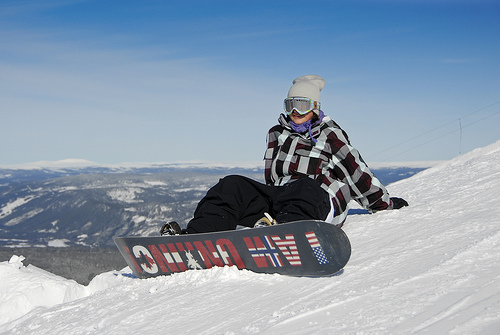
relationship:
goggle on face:
[275, 92, 317, 120] [273, 89, 323, 134]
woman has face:
[159, 73, 410, 240] [273, 89, 323, 134]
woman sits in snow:
[159, 73, 410, 240] [0, 139, 498, 334]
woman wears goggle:
[159, 73, 410, 240] [283, 96, 321, 115]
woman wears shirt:
[159, 73, 410, 240] [264, 114, 392, 226]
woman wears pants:
[159, 73, 410, 240] [184, 177, 329, 233]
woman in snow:
[159, 73, 410, 240] [0, 139, 498, 334]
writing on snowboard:
[121, 230, 329, 274] [108, 216, 354, 281]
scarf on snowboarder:
[274, 113, 335, 140] [174, 79, 427, 259]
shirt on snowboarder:
[242, 111, 413, 225] [161, 74, 409, 242]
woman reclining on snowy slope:
[159, 73, 410, 240] [28, 137, 496, 330]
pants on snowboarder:
[168, 167, 333, 245] [161, 74, 409, 242]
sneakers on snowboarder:
[154, 210, 281, 237] [161, 74, 409, 242]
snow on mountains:
[1, 156, 439, 245] [0, 155, 269, 252]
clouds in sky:
[75, 91, 189, 133] [70, 31, 182, 75]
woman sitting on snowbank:
[159, 73, 410, 240] [407, 158, 494, 335]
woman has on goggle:
[159, 73, 410, 240] [283, 96, 321, 115]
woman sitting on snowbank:
[159, 73, 410, 240] [53, 196, 470, 318]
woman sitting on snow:
[159, 73, 410, 240] [439, 136, 497, 228]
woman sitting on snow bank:
[159, 73, 410, 240] [1, 129, 496, 328]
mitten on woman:
[389, 196, 408, 209] [159, 73, 410, 240]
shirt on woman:
[242, 111, 413, 225] [159, 73, 410, 240]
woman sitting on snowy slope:
[159, 73, 410, 240] [0, 138, 500, 335]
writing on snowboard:
[121, 230, 329, 274] [112, 219, 352, 279]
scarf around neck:
[286, 109, 326, 143] [283, 117, 322, 131]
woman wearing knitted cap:
[159, 73, 410, 240] [279, 72, 326, 116]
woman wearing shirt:
[159, 73, 411, 240] [242, 111, 413, 225]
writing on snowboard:
[112, 234, 332, 274] [105, 222, 363, 287]